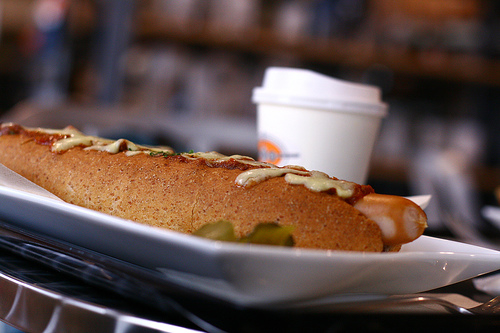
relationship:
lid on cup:
[249, 62, 393, 122] [249, 61, 391, 190]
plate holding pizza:
[1, 157, 500, 307] [0, 115, 438, 255]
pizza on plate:
[0, 115, 438, 255] [1, 157, 500, 307]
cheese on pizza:
[2, 117, 358, 199] [0, 115, 438, 255]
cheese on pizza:
[2, 117, 366, 203] [0, 115, 438, 255]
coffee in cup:
[255, 101, 387, 190] [249, 61, 391, 190]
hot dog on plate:
[346, 186, 434, 243] [1, 157, 500, 307]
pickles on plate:
[193, 212, 299, 251] [1, 157, 500, 307]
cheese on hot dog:
[2, 117, 358, 199] [346, 186, 434, 243]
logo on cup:
[251, 138, 287, 167] [249, 61, 391, 190]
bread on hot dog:
[0, 115, 403, 257] [346, 186, 434, 243]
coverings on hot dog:
[1, 121, 403, 259] [346, 186, 434, 243]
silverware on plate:
[267, 288, 496, 325] [1, 157, 500, 307]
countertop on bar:
[1, 241, 206, 332] [1, 0, 499, 332]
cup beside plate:
[249, 61, 391, 190] [1, 157, 500, 307]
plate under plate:
[1, 221, 271, 332] [1, 157, 500, 307]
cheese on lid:
[2, 117, 366, 203] [249, 62, 393, 122]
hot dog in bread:
[346, 186, 434, 243] [0, 115, 403, 257]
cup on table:
[249, 61, 391, 190] [0, 143, 499, 332]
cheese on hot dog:
[2, 117, 366, 203] [346, 186, 434, 243]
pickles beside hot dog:
[193, 212, 299, 251] [346, 186, 434, 243]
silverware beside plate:
[152, 275, 499, 331] [1, 157, 500, 307]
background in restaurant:
[1, 0, 500, 248] [1, 0, 500, 331]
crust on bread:
[0, 120, 384, 252] [0, 115, 403, 257]